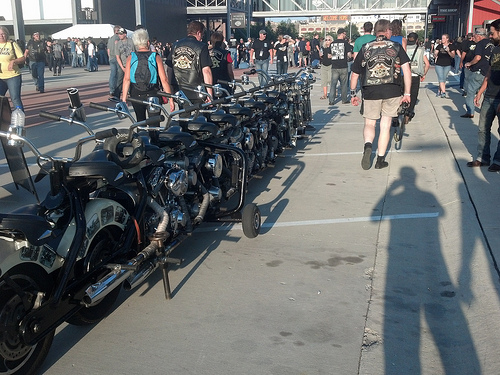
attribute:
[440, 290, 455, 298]
stain — oil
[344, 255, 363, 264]
stain — oil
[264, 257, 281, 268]
stain — oil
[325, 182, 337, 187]
stain — oil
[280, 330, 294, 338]
stain — oil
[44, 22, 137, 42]
tent — white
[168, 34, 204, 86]
jacket — leather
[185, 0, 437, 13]
walkway — metal, glass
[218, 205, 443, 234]
line — white, painted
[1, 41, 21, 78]
t-shirt — yellow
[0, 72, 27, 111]
jeans — blue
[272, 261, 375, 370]
pavement — gray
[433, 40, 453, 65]
t-shirt — black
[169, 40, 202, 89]
jacket — leather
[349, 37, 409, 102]
shirt — black